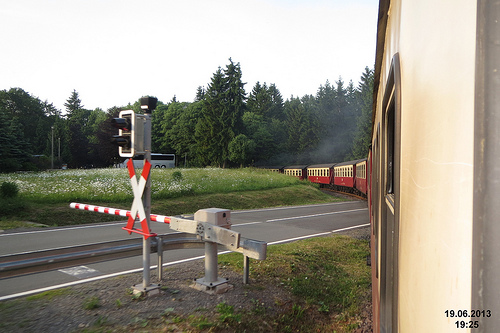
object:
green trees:
[226, 133, 260, 168]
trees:
[227, 132, 259, 168]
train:
[254, 0, 499, 332]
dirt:
[1, 227, 371, 332]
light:
[110, 116, 131, 128]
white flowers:
[70, 188, 76, 191]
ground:
[0, 167, 379, 332]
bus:
[113, 153, 177, 169]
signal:
[110, 108, 144, 158]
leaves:
[234, 100, 239, 105]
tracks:
[317, 186, 366, 200]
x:
[125, 157, 152, 239]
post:
[142, 113, 152, 286]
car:
[305, 163, 332, 185]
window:
[326, 168, 331, 178]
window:
[322, 168, 325, 176]